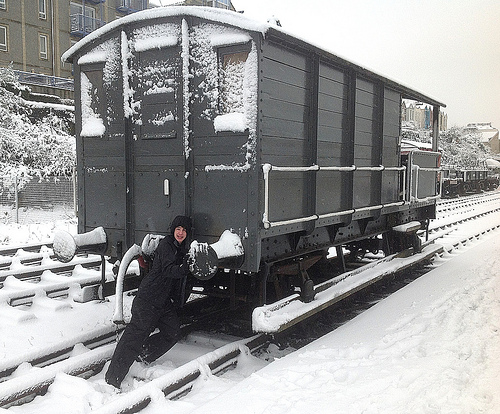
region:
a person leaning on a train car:
[42, 43, 479, 386]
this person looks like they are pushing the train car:
[25, 183, 293, 393]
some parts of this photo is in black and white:
[15, 5, 482, 334]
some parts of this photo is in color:
[18, 11, 491, 270]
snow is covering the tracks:
[15, 253, 234, 404]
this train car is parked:
[61, 66, 478, 334]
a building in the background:
[2, 4, 174, 100]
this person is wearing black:
[98, 208, 224, 381]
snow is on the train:
[50, 1, 330, 143]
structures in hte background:
[395, 83, 498, 145]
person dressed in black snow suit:
[102, 213, 194, 390]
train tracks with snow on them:
[428, 180, 498, 257]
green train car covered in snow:
[56, 2, 442, 312]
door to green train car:
[118, 22, 190, 254]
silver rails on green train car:
[261, 162, 453, 228]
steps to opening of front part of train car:
[394, 148, 427, 250]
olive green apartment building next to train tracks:
[1, 0, 253, 270]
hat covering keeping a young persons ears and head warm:
[165, 212, 195, 253]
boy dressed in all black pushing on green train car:
[50, 5, 446, 396]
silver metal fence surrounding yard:
[1, 163, 78, 225]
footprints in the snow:
[402, 310, 484, 370]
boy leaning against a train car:
[105, 206, 202, 411]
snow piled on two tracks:
[5, 337, 46, 388]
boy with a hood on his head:
[165, 211, 191, 246]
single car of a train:
[55, 5, 460, 225]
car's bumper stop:
[45, 220, 105, 260]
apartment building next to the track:
[2, 1, 78, 76]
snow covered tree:
[0, 86, 65, 201]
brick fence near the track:
[25, 175, 70, 205]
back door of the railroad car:
[125, 45, 185, 220]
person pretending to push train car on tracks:
[46, 7, 460, 408]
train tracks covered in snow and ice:
[446, 184, 497, 264]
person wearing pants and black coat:
[103, 212, 199, 397]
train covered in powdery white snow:
[48, 2, 277, 173]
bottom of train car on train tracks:
[225, 230, 445, 340]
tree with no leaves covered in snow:
[1, 40, 81, 260]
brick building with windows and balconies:
[1, 0, 93, 97]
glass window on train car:
[196, 37, 251, 149]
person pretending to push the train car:
[105, 215, 220, 398]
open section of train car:
[393, 87, 450, 230]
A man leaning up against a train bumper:
[104, 214, 243, 399]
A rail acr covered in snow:
[56, 4, 446, 336]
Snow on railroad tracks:
[0, 336, 87, 412]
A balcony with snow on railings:
[67, 1, 102, 34]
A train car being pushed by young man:
[61, 3, 448, 333]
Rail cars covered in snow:
[440, 158, 499, 198]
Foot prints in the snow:
[392, 286, 499, 392]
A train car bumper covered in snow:
[50, 221, 111, 263]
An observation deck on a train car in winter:
[370, 60, 498, 299]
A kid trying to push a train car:
[56, 5, 453, 405]